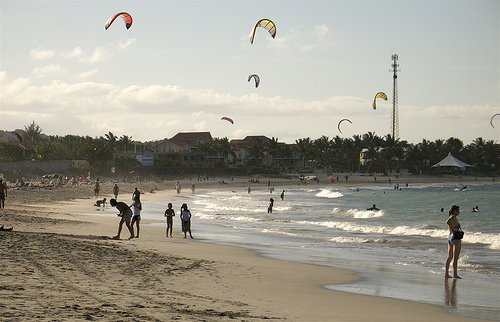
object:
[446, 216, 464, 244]
bikini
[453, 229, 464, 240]
bag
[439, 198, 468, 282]
person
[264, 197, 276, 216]
person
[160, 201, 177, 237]
person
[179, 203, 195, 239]
child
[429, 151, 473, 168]
top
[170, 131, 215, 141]
roof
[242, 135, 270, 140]
roof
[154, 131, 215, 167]
building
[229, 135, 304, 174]
building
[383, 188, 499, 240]
ocean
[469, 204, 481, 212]
people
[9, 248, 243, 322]
sand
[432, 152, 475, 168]
roof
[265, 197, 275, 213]
people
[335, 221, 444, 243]
waves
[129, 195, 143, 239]
people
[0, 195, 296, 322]
beach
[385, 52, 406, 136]
tower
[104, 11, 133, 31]
kite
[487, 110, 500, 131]
kite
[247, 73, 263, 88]
kite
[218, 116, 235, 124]
kite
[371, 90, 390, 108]
kite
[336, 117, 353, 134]
kite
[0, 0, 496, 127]
sky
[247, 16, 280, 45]
kite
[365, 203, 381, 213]
person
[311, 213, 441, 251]
water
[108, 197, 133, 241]
man